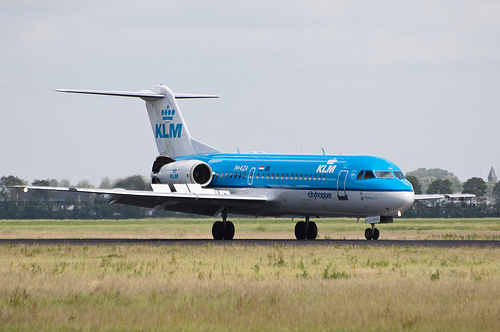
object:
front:
[308, 150, 415, 216]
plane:
[6, 83, 475, 240]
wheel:
[224, 219, 236, 240]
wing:
[7, 186, 265, 219]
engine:
[149, 159, 216, 189]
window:
[353, 169, 363, 181]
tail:
[54, 68, 228, 158]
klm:
[151, 122, 182, 139]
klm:
[313, 164, 337, 176]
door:
[334, 169, 349, 201]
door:
[244, 165, 256, 185]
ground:
[0, 216, 499, 332]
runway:
[0, 237, 499, 248]